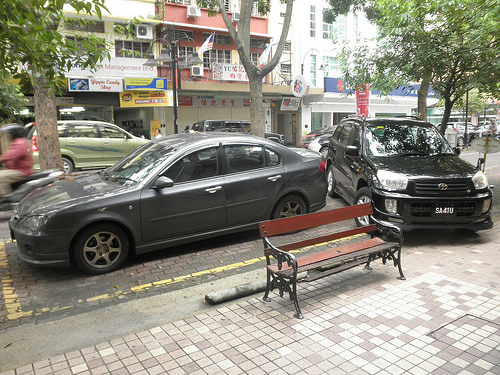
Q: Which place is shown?
A: It is a road.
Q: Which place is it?
A: It is a road.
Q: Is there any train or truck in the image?
A: No, there are no trains or trucks.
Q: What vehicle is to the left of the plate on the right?
A: The vehicle is a car.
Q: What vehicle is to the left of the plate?
A: The vehicle is a car.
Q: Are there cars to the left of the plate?
A: Yes, there is a car to the left of the plate.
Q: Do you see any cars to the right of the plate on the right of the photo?
A: No, the car is to the left of the plate.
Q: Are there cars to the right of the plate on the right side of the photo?
A: No, the car is to the left of the plate.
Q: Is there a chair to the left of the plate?
A: No, there is a car to the left of the plate.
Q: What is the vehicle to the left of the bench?
A: The vehicle is a car.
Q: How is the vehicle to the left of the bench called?
A: The vehicle is a car.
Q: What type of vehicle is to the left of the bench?
A: The vehicle is a car.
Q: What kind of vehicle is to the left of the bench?
A: The vehicle is a car.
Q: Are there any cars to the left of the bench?
A: Yes, there is a car to the left of the bench.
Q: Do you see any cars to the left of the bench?
A: Yes, there is a car to the left of the bench.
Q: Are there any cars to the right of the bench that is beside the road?
A: No, the car is to the left of the bench.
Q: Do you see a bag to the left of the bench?
A: No, there is a car to the left of the bench.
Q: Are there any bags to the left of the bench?
A: No, there is a car to the left of the bench.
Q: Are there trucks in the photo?
A: No, there are no trucks.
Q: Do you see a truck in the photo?
A: No, there are no trucks.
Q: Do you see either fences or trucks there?
A: No, there are no trucks or fences.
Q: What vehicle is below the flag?
A: The vehicle is a car.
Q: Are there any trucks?
A: No, there are no trucks.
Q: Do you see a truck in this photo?
A: No, there are no trucks.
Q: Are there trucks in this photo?
A: No, there are no trucks.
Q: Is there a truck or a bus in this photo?
A: No, there are no trucks or buses.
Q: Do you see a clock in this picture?
A: No, there are no clocks.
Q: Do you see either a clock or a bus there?
A: No, there are no clocks or buses.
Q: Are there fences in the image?
A: No, there are no fences.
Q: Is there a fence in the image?
A: No, there are no fences.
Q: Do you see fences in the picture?
A: No, there are no fences.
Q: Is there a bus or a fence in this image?
A: No, there are no fences or buses.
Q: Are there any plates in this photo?
A: Yes, there is a plate.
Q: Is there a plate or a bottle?
A: Yes, there is a plate.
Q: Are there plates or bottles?
A: Yes, there is a plate.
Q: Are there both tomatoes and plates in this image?
A: No, there is a plate but no tomatoes.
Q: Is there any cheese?
A: No, there is no cheese.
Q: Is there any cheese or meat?
A: No, there are no cheese or meat.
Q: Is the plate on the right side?
A: Yes, the plate is on the right of the image.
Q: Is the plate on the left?
A: No, the plate is on the right of the image.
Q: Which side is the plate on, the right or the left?
A: The plate is on the right of the image.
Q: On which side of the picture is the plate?
A: The plate is on the right of the image.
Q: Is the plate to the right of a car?
A: Yes, the plate is to the right of a car.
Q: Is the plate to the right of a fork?
A: No, the plate is to the right of a car.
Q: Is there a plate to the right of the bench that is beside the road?
A: Yes, there is a plate to the right of the bench.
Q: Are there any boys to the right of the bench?
A: No, there is a plate to the right of the bench.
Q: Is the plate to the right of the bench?
A: Yes, the plate is to the right of the bench.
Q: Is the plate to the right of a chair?
A: No, the plate is to the right of the bench.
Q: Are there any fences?
A: No, there are no fences.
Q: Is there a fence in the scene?
A: No, there are no fences.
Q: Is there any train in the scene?
A: No, there are no trains.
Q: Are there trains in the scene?
A: No, there are no trains.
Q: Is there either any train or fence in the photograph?
A: No, there are no trains or fences.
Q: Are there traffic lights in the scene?
A: No, there are no traffic lights.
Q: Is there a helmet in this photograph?
A: No, there are no helmets.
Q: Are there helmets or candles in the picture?
A: No, there are no helmets or candles.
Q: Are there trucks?
A: No, there are no trucks.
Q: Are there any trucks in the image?
A: No, there are no trucks.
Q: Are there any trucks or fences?
A: No, there are no trucks or fences.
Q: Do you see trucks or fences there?
A: No, there are no trucks or fences.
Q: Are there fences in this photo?
A: No, there are no fences.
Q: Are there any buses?
A: No, there are no buses.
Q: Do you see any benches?
A: Yes, there is a bench.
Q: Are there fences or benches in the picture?
A: Yes, there is a bench.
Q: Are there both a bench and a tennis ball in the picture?
A: No, there is a bench but no tennis balls.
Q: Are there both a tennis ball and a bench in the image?
A: No, there is a bench but no tennis balls.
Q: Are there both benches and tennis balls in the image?
A: No, there is a bench but no tennis balls.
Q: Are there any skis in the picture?
A: No, there are no skis.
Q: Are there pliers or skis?
A: No, there are no skis or pliers.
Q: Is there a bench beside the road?
A: Yes, there is a bench beside the road.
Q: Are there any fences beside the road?
A: No, there is a bench beside the road.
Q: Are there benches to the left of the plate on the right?
A: Yes, there is a bench to the left of the plate.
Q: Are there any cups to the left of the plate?
A: No, there is a bench to the left of the plate.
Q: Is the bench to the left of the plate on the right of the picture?
A: Yes, the bench is to the left of the plate.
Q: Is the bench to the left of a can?
A: No, the bench is to the left of the plate.